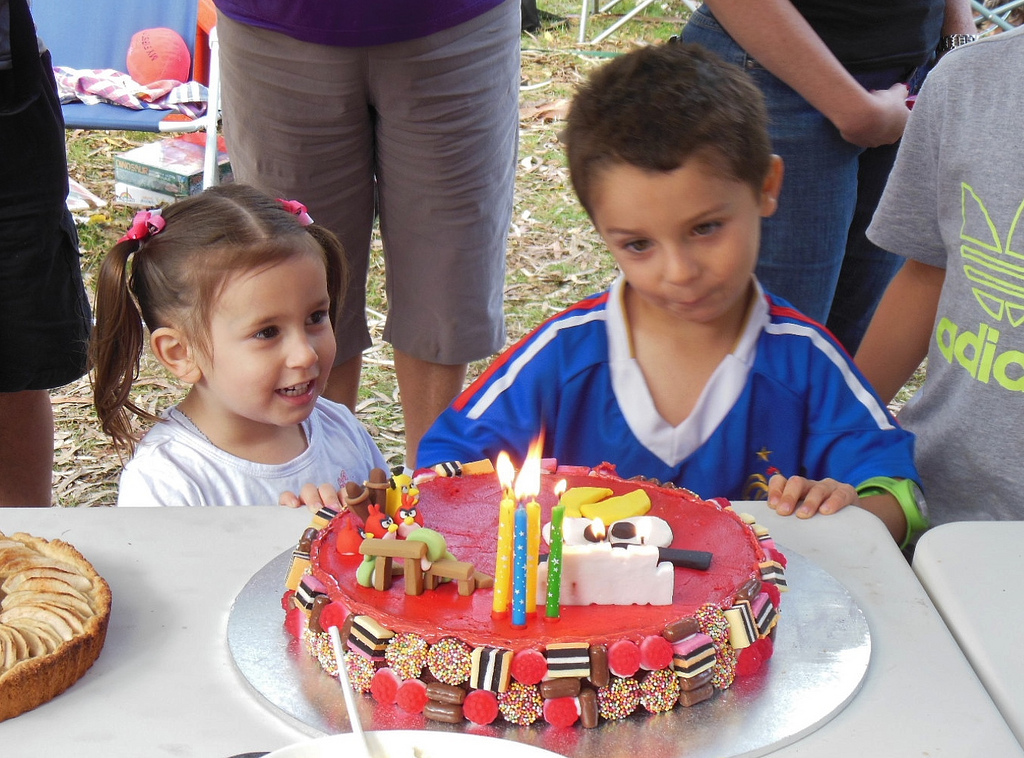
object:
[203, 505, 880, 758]
metal tray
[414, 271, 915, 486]
jersey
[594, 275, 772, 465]
collar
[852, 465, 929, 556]
watch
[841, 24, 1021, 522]
gray shirt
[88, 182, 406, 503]
girl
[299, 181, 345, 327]
pigtail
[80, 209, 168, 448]
pigtail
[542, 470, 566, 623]
candles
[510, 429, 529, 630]
candle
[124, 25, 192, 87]
balloon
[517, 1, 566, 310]
floor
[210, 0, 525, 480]
onlooker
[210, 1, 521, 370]
capris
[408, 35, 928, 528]
boy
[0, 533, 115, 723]
pastry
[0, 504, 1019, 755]
table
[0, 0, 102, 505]
person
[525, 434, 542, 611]
candle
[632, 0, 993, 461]
person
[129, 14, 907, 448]
outside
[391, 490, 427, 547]
animals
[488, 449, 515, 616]
candle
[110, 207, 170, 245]
barettes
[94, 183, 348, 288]
hair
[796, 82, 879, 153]
wrist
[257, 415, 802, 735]
birthday cake